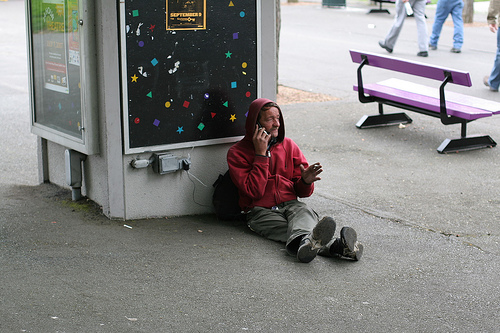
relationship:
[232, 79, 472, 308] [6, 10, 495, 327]
man sitting on ground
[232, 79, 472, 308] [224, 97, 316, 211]
man wearing hoodie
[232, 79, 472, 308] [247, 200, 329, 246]
man wearing pants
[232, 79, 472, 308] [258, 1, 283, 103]
man against pole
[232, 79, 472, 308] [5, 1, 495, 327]
man sitting on floor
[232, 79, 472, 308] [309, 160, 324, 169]
man holding cigarette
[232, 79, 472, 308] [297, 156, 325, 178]
man holding cigarette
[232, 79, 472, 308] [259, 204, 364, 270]
man wears pants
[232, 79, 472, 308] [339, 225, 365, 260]
man wears shoe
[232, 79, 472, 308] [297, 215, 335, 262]
man wears shoe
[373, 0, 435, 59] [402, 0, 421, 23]
man holds bottle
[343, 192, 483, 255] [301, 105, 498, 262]
crack on street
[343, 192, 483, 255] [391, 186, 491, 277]
crack on street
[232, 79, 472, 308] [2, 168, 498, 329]
man on ground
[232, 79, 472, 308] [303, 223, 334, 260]
man has feet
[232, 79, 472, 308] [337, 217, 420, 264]
man has feet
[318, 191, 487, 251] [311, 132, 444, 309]
line on ground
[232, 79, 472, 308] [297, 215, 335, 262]
man has shoe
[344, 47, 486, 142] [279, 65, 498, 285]
bench on ground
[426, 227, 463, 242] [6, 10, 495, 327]
crack on ground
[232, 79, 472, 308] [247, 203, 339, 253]
man has legs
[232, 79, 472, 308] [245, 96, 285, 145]
man has hood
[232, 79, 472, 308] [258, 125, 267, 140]
man talking on cellphone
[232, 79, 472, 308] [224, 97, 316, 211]
man in hoodie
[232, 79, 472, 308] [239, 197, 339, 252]
man in pants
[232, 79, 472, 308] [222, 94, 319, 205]
man wearing red hoodie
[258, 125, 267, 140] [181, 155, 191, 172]
cellphone plugged into outlet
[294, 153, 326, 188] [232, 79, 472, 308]
left hand on sitting man